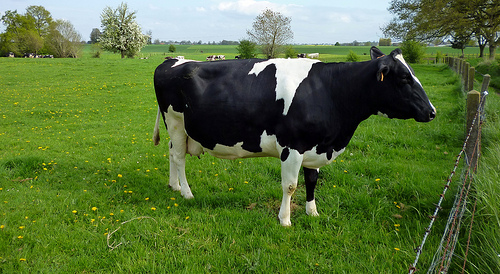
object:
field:
[0, 45, 498, 274]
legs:
[278, 148, 304, 217]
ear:
[370, 46, 386, 61]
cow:
[154, 45, 437, 227]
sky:
[0, 0, 500, 46]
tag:
[380, 73, 384, 82]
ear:
[376, 59, 392, 82]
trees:
[0, 9, 42, 57]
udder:
[185, 136, 207, 160]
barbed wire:
[409, 52, 491, 274]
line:
[393, 55, 437, 114]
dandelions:
[70, 204, 125, 223]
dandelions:
[40, 158, 60, 169]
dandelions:
[162, 195, 180, 211]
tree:
[91, 0, 149, 62]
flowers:
[13, 101, 21, 104]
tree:
[248, 8, 295, 58]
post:
[464, 90, 481, 171]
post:
[473, 73, 493, 112]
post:
[467, 64, 474, 90]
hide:
[150, 46, 435, 228]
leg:
[303, 165, 320, 211]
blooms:
[118, 174, 123, 178]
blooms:
[43, 167, 48, 171]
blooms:
[145, 197, 149, 200]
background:
[0, 0, 499, 58]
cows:
[205, 55, 225, 62]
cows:
[297, 53, 307, 59]